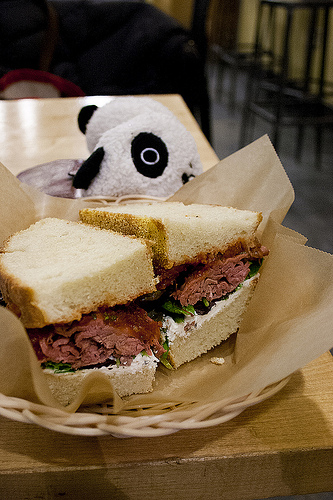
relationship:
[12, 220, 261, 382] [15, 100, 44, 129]
sandwhich on table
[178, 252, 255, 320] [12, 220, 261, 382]
meat in sandwhich